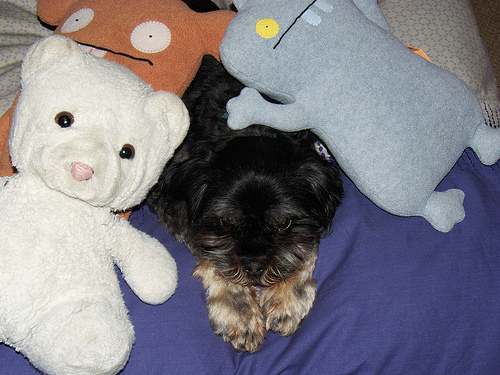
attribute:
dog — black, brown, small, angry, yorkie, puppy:
[144, 55, 344, 354]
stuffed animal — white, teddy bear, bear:
[0, 35, 190, 374]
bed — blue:
[2, 0, 499, 374]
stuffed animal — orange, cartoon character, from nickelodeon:
[1, 1, 237, 178]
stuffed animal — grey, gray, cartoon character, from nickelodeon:
[218, 2, 498, 235]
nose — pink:
[71, 161, 94, 183]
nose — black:
[245, 260, 264, 274]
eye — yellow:
[256, 17, 280, 40]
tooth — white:
[313, 0, 336, 11]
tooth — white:
[300, 8, 321, 26]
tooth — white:
[76, 41, 91, 52]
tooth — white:
[90, 46, 106, 58]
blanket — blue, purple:
[0, 148, 498, 375]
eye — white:
[131, 21, 173, 56]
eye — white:
[61, 7, 97, 33]